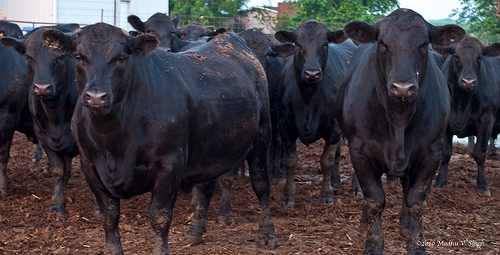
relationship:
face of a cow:
[273, 20, 349, 77] [278, 14, 403, 204]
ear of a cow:
[124, 28, 159, 55] [42, 22, 280, 250]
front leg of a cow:
[150, 165, 176, 254] [42, 22, 280, 250]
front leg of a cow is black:
[150, 165, 176, 254] [342, 6, 464, 252]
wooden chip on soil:
[340, 231, 353, 243] [306, 208, 362, 240]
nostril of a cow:
[97, 88, 107, 100] [42, 22, 280, 250]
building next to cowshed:
[239, 2, 281, 41] [0, 3, 168, 33]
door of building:
[1, 0, 57, 30] [239, 2, 281, 41]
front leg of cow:
[150, 165, 176, 254] [42, 22, 280, 250]